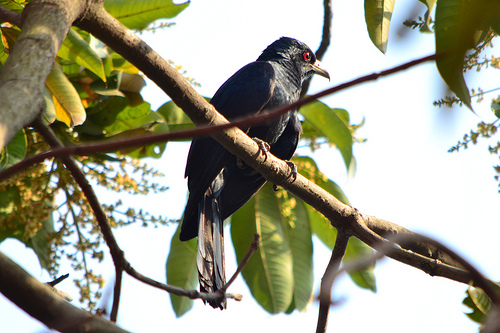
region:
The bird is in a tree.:
[0, 1, 499, 331]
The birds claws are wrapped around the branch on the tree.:
[245, 135, 301, 186]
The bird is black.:
[175, 25, 335, 306]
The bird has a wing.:
[170, 55, 276, 195]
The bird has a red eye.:
[298, 46, 313, 62]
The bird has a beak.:
[311, 55, 333, 82]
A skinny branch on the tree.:
[0, 35, 468, 196]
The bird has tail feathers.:
[190, 180, 225, 310]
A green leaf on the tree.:
[230, 177, 297, 314]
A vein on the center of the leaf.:
[250, 195, 277, 320]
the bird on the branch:
[187, 38, 339, 313]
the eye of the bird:
[294, 47, 314, 64]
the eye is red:
[301, 50, 312, 64]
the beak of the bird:
[307, 57, 335, 84]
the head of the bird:
[262, 29, 328, 99]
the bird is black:
[168, 30, 339, 323]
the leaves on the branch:
[230, 185, 381, 313]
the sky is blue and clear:
[369, 91, 490, 215]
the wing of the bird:
[168, 60, 281, 216]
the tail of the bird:
[182, 183, 246, 308]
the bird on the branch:
[184, 29, 344, 177]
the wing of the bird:
[207, 113, 319, 212]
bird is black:
[203, 26, 323, 294]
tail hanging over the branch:
[178, 151, 259, 331]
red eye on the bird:
[297, 44, 315, 63]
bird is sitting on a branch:
[175, 69, 422, 261]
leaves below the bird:
[180, 172, 408, 321]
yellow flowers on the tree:
[439, 36, 497, 156]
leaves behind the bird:
[58, 41, 208, 146]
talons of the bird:
[235, 127, 325, 187]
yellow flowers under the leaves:
[24, 144, 164, 296]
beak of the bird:
[302, 51, 349, 94]